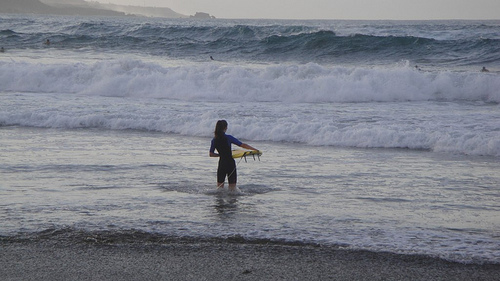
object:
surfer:
[209, 120, 260, 190]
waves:
[0, 92, 500, 155]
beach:
[0, 240, 500, 279]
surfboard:
[232, 150, 262, 157]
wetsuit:
[209, 135, 243, 184]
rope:
[216, 152, 246, 189]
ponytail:
[216, 120, 223, 143]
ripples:
[162, 180, 273, 196]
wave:
[0, 53, 499, 101]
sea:
[0, 17, 499, 265]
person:
[482, 67, 490, 71]